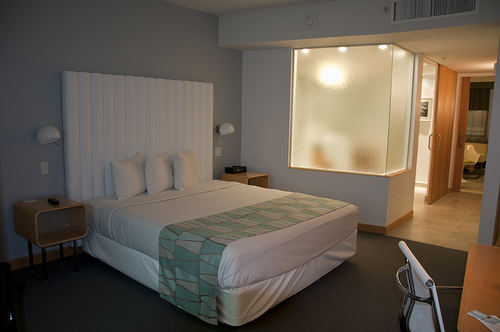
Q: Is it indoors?
A: Yes, it is indoors.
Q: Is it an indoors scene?
A: Yes, it is indoors.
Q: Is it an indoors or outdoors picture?
A: It is indoors.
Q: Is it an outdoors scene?
A: No, it is indoors.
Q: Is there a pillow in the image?
A: Yes, there is a pillow.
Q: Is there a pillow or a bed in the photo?
A: Yes, there is a pillow.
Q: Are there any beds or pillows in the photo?
A: Yes, there is a pillow.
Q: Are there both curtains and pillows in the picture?
A: No, there is a pillow but no curtains.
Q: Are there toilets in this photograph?
A: No, there are no toilets.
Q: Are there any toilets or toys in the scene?
A: No, there are no toilets or toys.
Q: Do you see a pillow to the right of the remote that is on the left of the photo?
A: Yes, there is a pillow to the right of the remote control.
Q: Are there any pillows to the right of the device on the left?
A: Yes, there is a pillow to the right of the remote control.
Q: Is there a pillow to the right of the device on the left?
A: Yes, there is a pillow to the right of the remote control.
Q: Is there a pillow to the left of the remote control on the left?
A: No, the pillow is to the right of the remote.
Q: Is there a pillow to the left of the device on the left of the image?
A: No, the pillow is to the right of the remote.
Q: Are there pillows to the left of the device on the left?
A: No, the pillow is to the right of the remote.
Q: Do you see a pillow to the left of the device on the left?
A: No, the pillow is to the right of the remote.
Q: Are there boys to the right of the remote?
A: No, there is a pillow to the right of the remote.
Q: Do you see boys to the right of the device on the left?
A: No, there is a pillow to the right of the remote.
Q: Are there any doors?
A: Yes, there is a door.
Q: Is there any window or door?
A: Yes, there is a door.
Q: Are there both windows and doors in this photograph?
A: Yes, there are both a door and windows.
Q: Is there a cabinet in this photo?
A: No, there are no cabinets.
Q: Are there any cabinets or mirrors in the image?
A: No, there are no cabinets or mirrors.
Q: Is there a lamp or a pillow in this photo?
A: Yes, there is a pillow.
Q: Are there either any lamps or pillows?
A: Yes, there is a pillow.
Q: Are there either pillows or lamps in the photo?
A: Yes, there is a pillow.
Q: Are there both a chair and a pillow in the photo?
A: Yes, there are both a pillow and a chair.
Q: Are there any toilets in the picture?
A: No, there are no toilets.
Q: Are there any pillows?
A: Yes, there is a pillow.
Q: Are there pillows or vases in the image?
A: Yes, there is a pillow.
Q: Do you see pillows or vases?
A: Yes, there is a pillow.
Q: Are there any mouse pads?
A: No, there are no mouse pads.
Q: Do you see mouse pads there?
A: No, there are no mouse pads.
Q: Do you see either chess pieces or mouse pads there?
A: No, there are no mouse pads or chess pieces.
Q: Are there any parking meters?
A: No, there are no parking meters.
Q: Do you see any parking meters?
A: No, there are no parking meters.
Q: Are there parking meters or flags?
A: No, there are no parking meters or flags.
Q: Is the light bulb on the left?
A: Yes, the light bulb is on the left of the image.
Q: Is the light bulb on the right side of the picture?
A: No, the light bulb is on the left of the image.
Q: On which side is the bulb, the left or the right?
A: The bulb is on the left of the image.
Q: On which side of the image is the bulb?
A: The bulb is on the left of the image.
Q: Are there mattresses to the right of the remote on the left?
A: Yes, there is a mattress to the right of the remote control.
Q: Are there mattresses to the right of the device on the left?
A: Yes, there is a mattress to the right of the remote control.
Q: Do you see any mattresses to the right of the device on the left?
A: Yes, there is a mattress to the right of the remote control.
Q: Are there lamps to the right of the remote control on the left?
A: No, there is a mattress to the right of the remote control.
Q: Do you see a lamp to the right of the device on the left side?
A: No, there is a mattress to the right of the remote control.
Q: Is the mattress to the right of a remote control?
A: Yes, the mattress is to the right of a remote control.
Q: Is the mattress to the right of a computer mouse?
A: No, the mattress is to the right of a remote control.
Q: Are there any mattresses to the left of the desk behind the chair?
A: Yes, there is a mattress to the left of the desk.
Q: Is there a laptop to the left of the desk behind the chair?
A: No, there is a mattress to the left of the desk.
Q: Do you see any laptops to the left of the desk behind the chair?
A: No, there is a mattress to the left of the desk.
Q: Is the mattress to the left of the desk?
A: Yes, the mattress is to the left of the desk.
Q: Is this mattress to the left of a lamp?
A: No, the mattress is to the left of the desk.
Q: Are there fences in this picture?
A: No, there are no fences.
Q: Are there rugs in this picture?
A: No, there are no rugs.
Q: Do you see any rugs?
A: No, there are no rugs.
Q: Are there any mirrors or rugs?
A: No, there are no rugs or mirrors.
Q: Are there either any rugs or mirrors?
A: No, there are no rugs or mirrors.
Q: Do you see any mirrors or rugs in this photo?
A: No, there are no rugs or mirrors.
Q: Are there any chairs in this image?
A: Yes, there is a chair.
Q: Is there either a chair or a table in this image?
A: Yes, there is a chair.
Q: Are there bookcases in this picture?
A: No, there are no bookcases.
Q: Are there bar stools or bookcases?
A: No, there are no bookcases or bar stools.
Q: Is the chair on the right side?
A: Yes, the chair is on the right of the image.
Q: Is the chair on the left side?
A: No, the chair is on the right of the image.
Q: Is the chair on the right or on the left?
A: The chair is on the right of the image.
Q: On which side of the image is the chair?
A: The chair is on the right of the image.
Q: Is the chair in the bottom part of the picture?
A: Yes, the chair is in the bottom of the image.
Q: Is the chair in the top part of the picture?
A: No, the chair is in the bottom of the image.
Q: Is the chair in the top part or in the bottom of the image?
A: The chair is in the bottom of the image.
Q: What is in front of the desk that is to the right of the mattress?
A: The chair is in front of the desk.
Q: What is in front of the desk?
A: The chair is in front of the desk.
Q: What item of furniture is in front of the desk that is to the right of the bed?
A: The piece of furniture is a chair.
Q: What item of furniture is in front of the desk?
A: The piece of furniture is a chair.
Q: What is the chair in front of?
A: The chair is in front of the desk.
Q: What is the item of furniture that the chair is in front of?
A: The piece of furniture is a desk.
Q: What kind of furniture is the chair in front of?
A: The chair is in front of the desk.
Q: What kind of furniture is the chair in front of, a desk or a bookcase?
A: The chair is in front of a desk.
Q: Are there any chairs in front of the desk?
A: Yes, there is a chair in front of the desk.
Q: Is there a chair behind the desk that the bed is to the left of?
A: No, the chair is in front of the desk.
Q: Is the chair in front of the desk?
A: Yes, the chair is in front of the desk.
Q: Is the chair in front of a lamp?
A: No, the chair is in front of the desk.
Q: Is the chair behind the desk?
A: No, the chair is in front of the desk.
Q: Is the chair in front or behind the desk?
A: The chair is in front of the desk.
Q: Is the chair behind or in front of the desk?
A: The chair is in front of the desk.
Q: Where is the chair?
A: The chair is at the desk.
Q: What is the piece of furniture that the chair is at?
A: The piece of furniture is a desk.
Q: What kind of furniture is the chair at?
A: The chair is at the desk.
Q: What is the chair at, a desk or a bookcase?
A: The chair is at a desk.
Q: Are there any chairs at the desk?
A: Yes, there is a chair at the desk.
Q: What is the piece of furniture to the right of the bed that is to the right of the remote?
A: The piece of furniture is a chair.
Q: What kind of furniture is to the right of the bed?
A: The piece of furniture is a chair.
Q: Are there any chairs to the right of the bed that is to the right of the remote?
A: Yes, there is a chair to the right of the bed.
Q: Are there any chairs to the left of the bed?
A: No, the chair is to the right of the bed.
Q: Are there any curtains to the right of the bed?
A: No, there is a chair to the right of the bed.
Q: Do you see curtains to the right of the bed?
A: No, there is a chair to the right of the bed.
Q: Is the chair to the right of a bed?
A: Yes, the chair is to the right of a bed.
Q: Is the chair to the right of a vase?
A: No, the chair is to the right of a bed.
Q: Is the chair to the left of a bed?
A: No, the chair is to the right of a bed.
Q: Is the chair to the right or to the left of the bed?
A: The chair is to the right of the bed.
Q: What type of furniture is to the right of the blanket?
A: The piece of furniture is a chair.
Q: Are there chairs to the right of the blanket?
A: Yes, there is a chair to the right of the blanket.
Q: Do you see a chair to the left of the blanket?
A: No, the chair is to the right of the blanket.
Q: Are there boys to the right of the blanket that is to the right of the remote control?
A: No, there is a chair to the right of the blanket.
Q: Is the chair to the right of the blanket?
A: Yes, the chair is to the right of the blanket.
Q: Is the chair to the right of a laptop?
A: No, the chair is to the right of the blanket.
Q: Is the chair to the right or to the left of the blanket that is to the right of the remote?
A: The chair is to the right of the blanket.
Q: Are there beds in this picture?
A: Yes, there is a bed.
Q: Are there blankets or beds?
A: Yes, there is a bed.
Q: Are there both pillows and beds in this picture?
A: Yes, there are both a bed and a pillow.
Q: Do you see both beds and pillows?
A: Yes, there are both a bed and a pillow.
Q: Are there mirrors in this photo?
A: No, there are no mirrors.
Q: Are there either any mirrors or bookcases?
A: No, there are no mirrors or bookcases.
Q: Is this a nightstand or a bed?
A: This is a bed.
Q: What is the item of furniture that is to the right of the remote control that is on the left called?
A: The piece of furniture is a bed.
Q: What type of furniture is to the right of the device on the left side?
A: The piece of furniture is a bed.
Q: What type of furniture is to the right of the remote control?
A: The piece of furniture is a bed.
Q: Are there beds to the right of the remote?
A: Yes, there is a bed to the right of the remote.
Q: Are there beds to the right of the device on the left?
A: Yes, there is a bed to the right of the remote.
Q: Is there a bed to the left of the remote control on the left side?
A: No, the bed is to the right of the remote.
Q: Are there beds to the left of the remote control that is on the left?
A: No, the bed is to the right of the remote.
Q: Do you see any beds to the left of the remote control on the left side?
A: No, the bed is to the right of the remote.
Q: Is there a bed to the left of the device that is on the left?
A: No, the bed is to the right of the remote.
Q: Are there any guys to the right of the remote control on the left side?
A: No, there is a bed to the right of the remote control.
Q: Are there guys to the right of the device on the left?
A: No, there is a bed to the right of the remote control.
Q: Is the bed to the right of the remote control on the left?
A: Yes, the bed is to the right of the remote control.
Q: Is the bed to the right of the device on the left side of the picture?
A: Yes, the bed is to the right of the remote control.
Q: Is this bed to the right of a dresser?
A: No, the bed is to the right of the remote control.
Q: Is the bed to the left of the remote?
A: No, the bed is to the right of the remote.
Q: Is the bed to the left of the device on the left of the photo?
A: No, the bed is to the right of the remote.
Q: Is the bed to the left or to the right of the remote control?
A: The bed is to the right of the remote control.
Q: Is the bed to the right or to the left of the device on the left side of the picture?
A: The bed is to the right of the remote control.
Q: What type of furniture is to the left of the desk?
A: The piece of furniture is a bed.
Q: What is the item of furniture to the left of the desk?
A: The piece of furniture is a bed.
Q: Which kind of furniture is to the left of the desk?
A: The piece of furniture is a bed.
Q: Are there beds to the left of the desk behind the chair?
A: Yes, there is a bed to the left of the desk.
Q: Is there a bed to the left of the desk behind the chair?
A: Yes, there is a bed to the left of the desk.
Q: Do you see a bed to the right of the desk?
A: No, the bed is to the left of the desk.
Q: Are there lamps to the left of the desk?
A: No, there is a bed to the left of the desk.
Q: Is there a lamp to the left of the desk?
A: No, there is a bed to the left of the desk.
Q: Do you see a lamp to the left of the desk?
A: No, there is a bed to the left of the desk.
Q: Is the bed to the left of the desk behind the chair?
A: Yes, the bed is to the left of the desk.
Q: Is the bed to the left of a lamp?
A: No, the bed is to the left of the desk.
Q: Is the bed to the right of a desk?
A: No, the bed is to the left of a desk.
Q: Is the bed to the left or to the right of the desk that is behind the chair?
A: The bed is to the left of the desk.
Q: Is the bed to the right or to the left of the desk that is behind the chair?
A: The bed is to the left of the desk.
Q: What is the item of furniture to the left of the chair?
A: The piece of furniture is a bed.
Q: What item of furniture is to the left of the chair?
A: The piece of furniture is a bed.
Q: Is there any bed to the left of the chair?
A: Yes, there is a bed to the left of the chair.